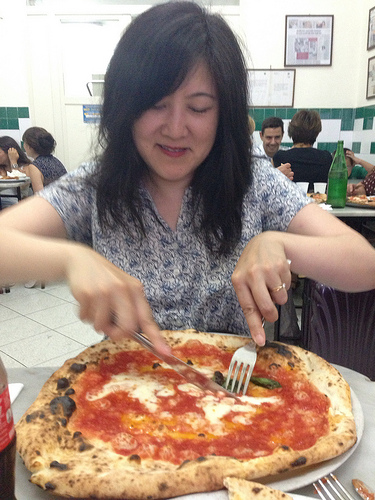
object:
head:
[101, 1, 249, 183]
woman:
[0, 0, 375, 365]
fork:
[224, 258, 293, 395]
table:
[0, 357, 375, 500]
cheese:
[85, 368, 280, 426]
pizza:
[15, 328, 357, 492]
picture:
[283, 13, 335, 67]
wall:
[249, 0, 373, 150]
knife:
[351, 479, 373, 499]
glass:
[327, 138, 349, 208]